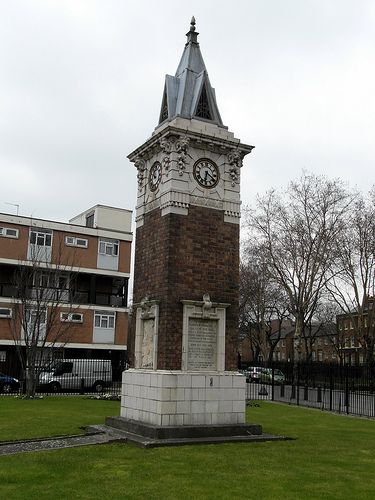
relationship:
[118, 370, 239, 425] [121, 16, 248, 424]
base on tower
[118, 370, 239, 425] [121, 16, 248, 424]
base of tower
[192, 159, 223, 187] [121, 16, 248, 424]
clock on tower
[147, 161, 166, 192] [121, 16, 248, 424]
clock on tower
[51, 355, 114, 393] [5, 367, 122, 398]
van on street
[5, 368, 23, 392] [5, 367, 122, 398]
car on street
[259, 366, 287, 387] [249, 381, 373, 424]
car on street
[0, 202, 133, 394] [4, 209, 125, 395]
building on building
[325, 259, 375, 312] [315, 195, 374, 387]
branches on tree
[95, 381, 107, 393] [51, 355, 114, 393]
wheel on van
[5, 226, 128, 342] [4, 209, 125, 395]
windows on building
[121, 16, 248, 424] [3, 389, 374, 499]
tower in grass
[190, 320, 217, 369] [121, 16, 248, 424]
writing on tower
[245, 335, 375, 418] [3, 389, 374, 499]
fence around grass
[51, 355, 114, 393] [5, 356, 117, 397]
van behind fence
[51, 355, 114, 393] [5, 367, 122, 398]
van near street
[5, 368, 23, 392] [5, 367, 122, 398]
car near street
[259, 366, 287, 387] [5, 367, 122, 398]
car near street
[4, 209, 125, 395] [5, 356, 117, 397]
building behind fence